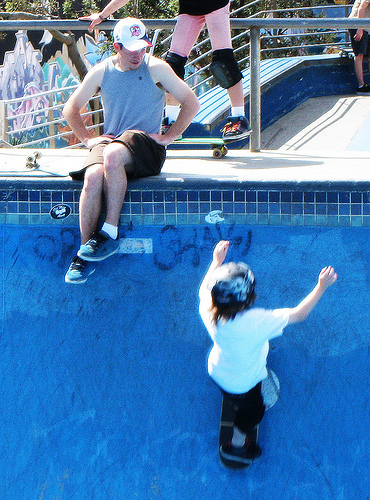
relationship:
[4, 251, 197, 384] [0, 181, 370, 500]
wall part of pool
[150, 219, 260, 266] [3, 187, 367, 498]
black graffiti written on wall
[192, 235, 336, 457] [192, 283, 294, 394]
boy wearing white shirt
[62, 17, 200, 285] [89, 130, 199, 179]
adult wearing shorts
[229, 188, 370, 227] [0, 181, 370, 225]
tile part of tile border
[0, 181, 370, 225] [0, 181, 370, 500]
tile border part of pool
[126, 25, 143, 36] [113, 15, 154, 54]
logo part of hat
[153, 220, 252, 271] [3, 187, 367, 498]
black graffiti painted on wall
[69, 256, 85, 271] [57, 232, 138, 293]
laces part of sneaker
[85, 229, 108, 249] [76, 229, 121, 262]
laces part of sneaker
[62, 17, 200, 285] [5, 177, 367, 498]
adult sitting on pool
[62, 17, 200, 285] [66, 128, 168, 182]
adult wearing shorts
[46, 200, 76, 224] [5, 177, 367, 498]
sticker on pool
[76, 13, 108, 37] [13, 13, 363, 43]
hand on rail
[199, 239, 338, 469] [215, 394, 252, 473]
boy on skateboard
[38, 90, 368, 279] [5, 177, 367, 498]
wall in pool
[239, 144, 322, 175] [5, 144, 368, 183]
shadow on ground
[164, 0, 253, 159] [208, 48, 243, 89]
person wearing knee pad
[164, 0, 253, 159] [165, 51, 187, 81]
person wearing knee pad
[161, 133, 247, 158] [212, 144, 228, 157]
green skateboard has yellow wheels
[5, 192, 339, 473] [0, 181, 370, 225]
pool has tile border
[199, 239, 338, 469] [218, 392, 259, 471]
boy on skateboard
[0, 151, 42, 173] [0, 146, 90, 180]
skateboard on ground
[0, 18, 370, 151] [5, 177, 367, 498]
railing on pool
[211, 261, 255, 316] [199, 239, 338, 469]
head on boy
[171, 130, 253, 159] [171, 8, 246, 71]
green skateboard wearing pink leggings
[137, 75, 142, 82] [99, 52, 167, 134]
symbol on t shirt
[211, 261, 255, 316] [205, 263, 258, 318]
head on a head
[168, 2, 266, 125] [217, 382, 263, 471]
person on a skateboard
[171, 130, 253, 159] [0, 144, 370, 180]
green skateboard on a ground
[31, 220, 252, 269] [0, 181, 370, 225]
graffiti on tile border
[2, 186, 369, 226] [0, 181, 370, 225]
tile border on tile border